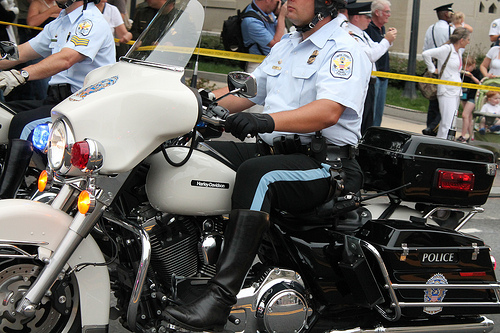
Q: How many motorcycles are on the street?
A: Two.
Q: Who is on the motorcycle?
A: A man.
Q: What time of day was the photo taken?
A: Daytime.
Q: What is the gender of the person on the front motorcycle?
A: Male.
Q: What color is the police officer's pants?
A: Black and blue.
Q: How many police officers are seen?
A: Two.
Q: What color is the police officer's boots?
A: Black.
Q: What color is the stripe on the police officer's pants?
A: Blue.